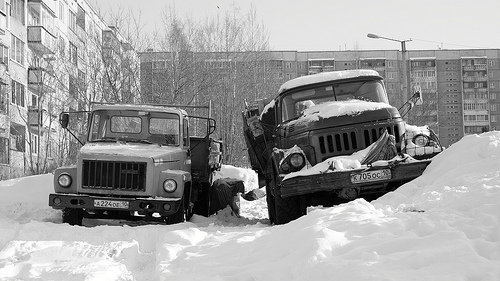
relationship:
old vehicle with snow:
[237, 69, 440, 219] [302, 99, 383, 119]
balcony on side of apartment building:
[17, 18, 57, 63] [1, 0, 140, 180]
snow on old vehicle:
[286, 197, 463, 265] [241, 69, 446, 225]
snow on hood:
[286, 197, 463, 265] [274, 96, 401, 134]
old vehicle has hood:
[241, 69, 446, 225] [274, 96, 401, 134]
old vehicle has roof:
[241, 69, 446, 225] [273, 68, 380, 90]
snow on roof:
[0, 68, 499, 280] [273, 68, 380, 90]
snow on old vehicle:
[0, 68, 499, 280] [241, 69, 446, 225]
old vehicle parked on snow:
[241, 69, 446, 225] [4, 127, 496, 279]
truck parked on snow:
[49, 100, 246, 228] [4, 127, 496, 279]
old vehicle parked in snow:
[241, 69, 446, 225] [4, 127, 496, 279]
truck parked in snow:
[49, 100, 246, 228] [4, 127, 496, 279]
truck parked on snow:
[45, 99, 220, 224] [345, 189, 480, 256]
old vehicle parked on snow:
[241, 69, 446, 225] [345, 189, 480, 256]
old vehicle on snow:
[241, 69, 446, 225] [343, 178, 477, 261]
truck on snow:
[49, 100, 246, 228] [10, 220, 499, 277]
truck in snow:
[49, 100, 246, 228] [0, 225, 500, 276]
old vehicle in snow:
[241, 69, 446, 225] [0, 225, 500, 276]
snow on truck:
[0, 68, 499, 280] [45, 93, 259, 234]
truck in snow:
[49, 100, 246, 228] [4, 127, 496, 279]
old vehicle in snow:
[241, 69, 446, 225] [269, 211, 469, 259]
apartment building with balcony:
[1, 4, 140, 191] [24, 24, 54, 56]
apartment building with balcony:
[1, 4, 140, 191] [30, 64, 58, 94]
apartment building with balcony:
[1, 4, 140, 191] [30, 105, 56, 137]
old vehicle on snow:
[241, 69, 446, 225] [262, 219, 495, 258]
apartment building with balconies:
[1, 0, 140, 180] [22, 5, 302, 187]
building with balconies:
[137, 46, 499, 166] [22, 5, 302, 187]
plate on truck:
[82, 184, 144, 209] [51, 93, 218, 228]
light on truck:
[281, 154, 306, 169] [248, 74, 443, 203]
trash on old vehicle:
[359, 125, 398, 177] [241, 69, 446, 225]